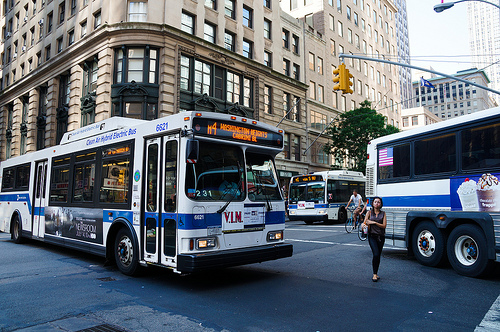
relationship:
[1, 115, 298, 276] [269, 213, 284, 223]
bus has blue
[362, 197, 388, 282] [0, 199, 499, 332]
lady crossing road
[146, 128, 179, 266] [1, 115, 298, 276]
doors on bus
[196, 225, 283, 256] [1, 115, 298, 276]
headlights on bus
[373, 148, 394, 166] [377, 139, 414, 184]
flag on window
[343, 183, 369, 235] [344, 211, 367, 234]
man on bicycle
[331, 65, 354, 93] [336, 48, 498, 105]
stoplight on pole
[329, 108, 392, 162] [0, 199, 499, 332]
tree by road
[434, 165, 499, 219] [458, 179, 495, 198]
advertisement for icecream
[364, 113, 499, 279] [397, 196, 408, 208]
bus has blue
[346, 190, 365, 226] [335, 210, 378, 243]
man on bike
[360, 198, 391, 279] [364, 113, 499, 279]
lady by bus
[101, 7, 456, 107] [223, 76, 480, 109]
buildings in row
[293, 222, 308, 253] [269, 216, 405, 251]
lines for crosswalk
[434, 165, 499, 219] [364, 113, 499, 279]
photo on bus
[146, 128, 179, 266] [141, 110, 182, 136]
door has 6621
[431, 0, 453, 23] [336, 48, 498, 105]
light on pole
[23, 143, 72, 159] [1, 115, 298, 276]
edge of bus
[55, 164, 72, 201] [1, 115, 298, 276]
window on bus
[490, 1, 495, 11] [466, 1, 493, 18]
metal on pole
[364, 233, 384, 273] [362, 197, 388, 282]
jeans on lady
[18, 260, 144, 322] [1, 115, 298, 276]
road by bus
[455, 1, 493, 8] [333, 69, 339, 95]
pole above light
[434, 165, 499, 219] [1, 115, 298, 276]
advertisement on bus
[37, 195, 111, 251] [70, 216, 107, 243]
advertisement for show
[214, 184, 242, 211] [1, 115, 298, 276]
wiper for bus